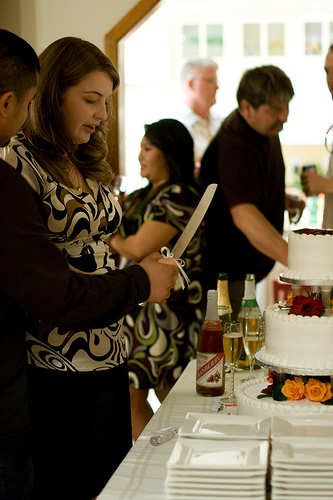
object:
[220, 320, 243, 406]
champagne glass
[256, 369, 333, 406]
flowers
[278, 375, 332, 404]
roses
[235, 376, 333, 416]
cake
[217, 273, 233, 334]
bottle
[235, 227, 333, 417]
cake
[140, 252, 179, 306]
hand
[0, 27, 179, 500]
man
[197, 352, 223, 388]
label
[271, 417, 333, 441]
plate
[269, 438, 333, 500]
plate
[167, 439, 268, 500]
plate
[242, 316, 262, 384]
champagne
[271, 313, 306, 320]
frosting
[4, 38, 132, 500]
woman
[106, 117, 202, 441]
woman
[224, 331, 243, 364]
drink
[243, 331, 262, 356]
drink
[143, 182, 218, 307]
cake knife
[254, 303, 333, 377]
cake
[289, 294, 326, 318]
floewr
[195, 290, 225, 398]
bottle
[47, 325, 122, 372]
design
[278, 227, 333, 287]
cake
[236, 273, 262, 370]
bottles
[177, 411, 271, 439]
plate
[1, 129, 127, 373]
shirt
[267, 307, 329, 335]
frosting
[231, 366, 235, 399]
handle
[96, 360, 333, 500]
table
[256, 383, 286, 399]
leaves